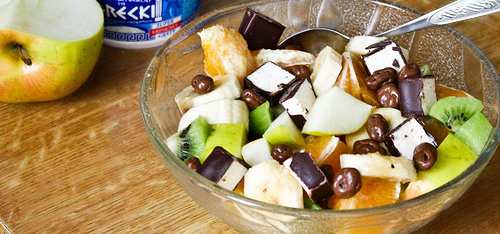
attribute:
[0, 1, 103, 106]
apple — cut, green, yellow, red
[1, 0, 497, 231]
table — wooden, wood, brown, smooth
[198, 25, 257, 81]
piece — orange, sliced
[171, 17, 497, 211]
salad — fruit, mixed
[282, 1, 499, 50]
spoon — silver, steel, stainless, metal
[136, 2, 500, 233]
bowl — clear, glass, large, full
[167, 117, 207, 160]
piece — kiwi, green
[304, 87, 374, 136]
slice — apple, sliced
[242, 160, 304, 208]
piece — banana, sliced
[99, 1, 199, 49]
container — bottom , yogurt , blue, white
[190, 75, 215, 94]
raisin — covered, raisins, brown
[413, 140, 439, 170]
chocolate — covered, raisins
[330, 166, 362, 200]
chocolate — covered, raisins, brown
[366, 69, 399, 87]
chocolate — covered, raisins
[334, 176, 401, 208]
slice — orange, sliced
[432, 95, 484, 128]
kiwi — green, sliced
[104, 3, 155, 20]
lettering — white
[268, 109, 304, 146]
wedge — pear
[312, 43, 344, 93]
banana — sliced, white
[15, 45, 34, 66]
stem — brown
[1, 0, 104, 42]
flesh — white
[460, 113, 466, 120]
seed — black